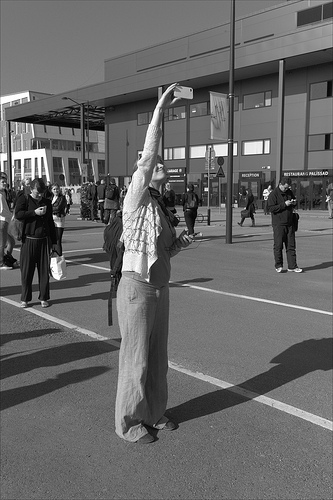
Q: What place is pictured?
A: It is a road.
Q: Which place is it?
A: It is a road.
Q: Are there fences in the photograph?
A: No, there are no fences.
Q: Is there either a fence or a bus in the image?
A: No, there are no fences or buses.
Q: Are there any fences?
A: No, there are no fences.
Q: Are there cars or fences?
A: No, there are no fences or cars.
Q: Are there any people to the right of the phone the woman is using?
A: Yes, there are people to the right of the phone.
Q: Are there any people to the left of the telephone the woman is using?
A: No, the people are to the right of the telephone.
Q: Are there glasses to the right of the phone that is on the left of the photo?
A: No, there are people to the right of the telephone.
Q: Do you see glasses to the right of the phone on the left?
A: No, there are people to the right of the telephone.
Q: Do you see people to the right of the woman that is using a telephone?
A: Yes, there are people to the right of the woman.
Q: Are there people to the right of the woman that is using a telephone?
A: Yes, there are people to the right of the woman.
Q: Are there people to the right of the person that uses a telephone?
A: Yes, there are people to the right of the woman.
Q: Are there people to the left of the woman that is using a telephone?
A: No, the people are to the right of the woman.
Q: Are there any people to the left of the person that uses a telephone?
A: No, the people are to the right of the woman.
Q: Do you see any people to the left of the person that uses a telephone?
A: No, the people are to the right of the woman.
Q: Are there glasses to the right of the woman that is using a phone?
A: No, there are people to the right of the woman.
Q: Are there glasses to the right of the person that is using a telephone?
A: No, there are people to the right of the woman.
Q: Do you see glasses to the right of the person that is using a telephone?
A: No, there are people to the right of the woman.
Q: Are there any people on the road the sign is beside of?
A: Yes, there are people on the road.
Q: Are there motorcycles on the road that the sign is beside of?
A: No, there are people on the road.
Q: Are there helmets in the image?
A: No, there are no helmets.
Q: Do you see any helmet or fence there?
A: No, there are no helmets or fences.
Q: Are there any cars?
A: No, there are no cars.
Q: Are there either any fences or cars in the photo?
A: No, there are no cars or fences.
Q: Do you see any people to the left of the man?
A: Yes, there is a person to the left of the man.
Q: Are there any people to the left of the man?
A: Yes, there is a person to the left of the man.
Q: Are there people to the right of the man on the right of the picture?
A: No, the person is to the left of the man.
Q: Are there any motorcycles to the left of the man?
A: No, there is a person to the left of the man.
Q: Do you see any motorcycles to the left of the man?
A: No, there is a person to the left of the man.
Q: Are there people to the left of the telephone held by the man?
A: Yes, there is a person to the left of the phone.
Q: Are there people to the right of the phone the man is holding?
A: No, the person is to the left of the telephone.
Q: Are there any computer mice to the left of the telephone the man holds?
A: No, there is a person to the left of the phone.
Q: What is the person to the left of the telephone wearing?
A: The person is wearing a bag.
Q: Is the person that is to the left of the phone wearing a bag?
A: Yes, the person is wearing a bag.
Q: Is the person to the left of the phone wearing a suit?
A: No, the person is wearing a bag.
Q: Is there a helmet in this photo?
A: No, there are no helmets.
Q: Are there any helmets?
A: No, there are no helmets.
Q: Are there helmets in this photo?
A: No, there are no helmets.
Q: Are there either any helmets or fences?
A: No, there are no helmets or fences.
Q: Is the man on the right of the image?
A: Yes, the man is on the right of the image.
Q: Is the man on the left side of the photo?
A: No, the man is on the right of the image.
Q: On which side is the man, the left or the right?
A: The man is on the right of the image.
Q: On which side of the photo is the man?
A: The man is on the right of the image.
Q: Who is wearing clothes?
A: The man is wearing clothes.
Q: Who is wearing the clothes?
A: The man is wearing clothes.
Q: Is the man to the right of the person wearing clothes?
A: Yes, the man is wearing clothes.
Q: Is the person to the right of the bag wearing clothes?
A: Yes, the man is wearing clothes.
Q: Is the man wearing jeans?
A: No, the man is wearing clothes.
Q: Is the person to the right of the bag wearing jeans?
A: No, the man is wearing clothes.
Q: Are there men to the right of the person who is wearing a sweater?
A: Yes, there is a man to the right of the person.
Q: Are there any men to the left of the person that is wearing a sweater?
A: No, the man is to the right of the person.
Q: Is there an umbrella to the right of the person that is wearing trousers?
A: No, there is a man to the right of the person.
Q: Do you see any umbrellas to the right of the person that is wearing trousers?
A: No, there is a man to the right of the person.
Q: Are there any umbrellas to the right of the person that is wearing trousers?
A: No, there is a man to the right of the person.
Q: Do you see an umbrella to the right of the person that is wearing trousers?
A: No, there is a man to the right of the person.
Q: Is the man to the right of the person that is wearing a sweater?
A: Yes, the man is to the right of the person.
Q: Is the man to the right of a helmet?
A: No, the man is to the right of the person.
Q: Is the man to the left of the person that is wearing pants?
A: No, the man is to the right of the person.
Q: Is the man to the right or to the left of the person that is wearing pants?
A: The man is to the right of the person.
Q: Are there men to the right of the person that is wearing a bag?
A: Yes, there is a man to the right of the person.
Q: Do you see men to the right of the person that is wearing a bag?
A: Yes, there is a man to the right of the person.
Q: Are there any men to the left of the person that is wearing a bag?
A: No, the man is to the right of the person.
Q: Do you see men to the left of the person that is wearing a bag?
A: No, the man is to the right of the person.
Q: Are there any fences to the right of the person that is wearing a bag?
A: No, there is a man to the right of the person.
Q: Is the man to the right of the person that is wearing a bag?
A: Yes, the man is to the right of the person.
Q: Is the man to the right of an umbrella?
A: No, the man is to the right of the person.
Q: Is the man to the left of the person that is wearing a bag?
A: No, the man is to the right of the person.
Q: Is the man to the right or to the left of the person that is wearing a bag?
A: The man is to the right of the person.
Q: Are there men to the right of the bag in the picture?
A: Yes, there is a man to the right of the bag.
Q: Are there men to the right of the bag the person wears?
A: Yes, there is a man to the right of the bag.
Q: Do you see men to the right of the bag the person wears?
A: Yes, there is a man to the right of the bag.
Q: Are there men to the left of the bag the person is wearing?
A: No, the man is to the right of the bag.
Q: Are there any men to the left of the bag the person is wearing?
A: No, the man is to the right of the bag.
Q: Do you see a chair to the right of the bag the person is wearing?
A: No, there is a man to the right of the bag.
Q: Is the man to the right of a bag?
A: Yes, the man is to the right of a bag.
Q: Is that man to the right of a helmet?
A: No, the man is to the right of a bag.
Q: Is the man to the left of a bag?
A: No, the man is to the right of a bag.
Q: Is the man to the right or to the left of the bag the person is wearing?
A: The man is to the right of the bag.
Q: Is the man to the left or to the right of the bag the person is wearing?
A: The man is to the right of the bag.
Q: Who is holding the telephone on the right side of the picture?
A: The man is holding the telephone.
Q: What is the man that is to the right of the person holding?
A: The man is holding the telephone.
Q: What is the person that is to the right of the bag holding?
A: The man is holding the telephone.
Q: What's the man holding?
A: The man is holding the telephone.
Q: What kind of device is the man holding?
A: The man is holding the phone.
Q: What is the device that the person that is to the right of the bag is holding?
A: The device is a phone.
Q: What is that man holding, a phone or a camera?
A: The man is holding a phone.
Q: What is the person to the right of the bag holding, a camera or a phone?
A: The man is holding a phone.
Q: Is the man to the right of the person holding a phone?
A: Yes, the man is holding a phone.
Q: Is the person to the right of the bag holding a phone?
A: Yes, the man is holding a phone.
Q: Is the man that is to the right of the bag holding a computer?
A: No, the man is holding a phone.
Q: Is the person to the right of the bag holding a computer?
A: No, the man is holding a phone.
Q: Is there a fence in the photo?
A: No, there are no fences.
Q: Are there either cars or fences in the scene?
A: No, there are no fences or cars.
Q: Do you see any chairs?
A: No, there are no chairs.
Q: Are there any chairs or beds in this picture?
A: No, there are no chairs or beds.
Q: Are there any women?
A: Yes, there is a woman.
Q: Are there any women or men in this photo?
A: Yes, there is a woman.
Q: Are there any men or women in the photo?
A: Yes, there is a woman.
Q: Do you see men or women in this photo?
A: Yes, there is a woman.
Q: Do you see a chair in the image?
A: No, there are no chairs.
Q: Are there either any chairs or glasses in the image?
A: No, there are no chairs or glasses.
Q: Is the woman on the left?
A: Yes, the woman is on the left of the image.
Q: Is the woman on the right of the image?
A: No, the woman is on the left of the image.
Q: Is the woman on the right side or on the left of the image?
A: The woman is on the left of the image.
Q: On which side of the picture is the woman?
A: The woman is on the left of the image.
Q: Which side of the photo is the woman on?
A: The woman is on the left of the image.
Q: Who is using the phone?
A: The woman is using the phone.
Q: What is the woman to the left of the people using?
A: The woman is using a phone.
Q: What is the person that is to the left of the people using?
A: The woman is using a phone.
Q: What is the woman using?
A: The woman is using a phone.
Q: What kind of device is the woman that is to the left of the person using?
A: The woman is using a telephone.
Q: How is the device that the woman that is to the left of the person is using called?
A: The device is a phone.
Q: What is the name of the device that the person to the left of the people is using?
A: The device is a phone.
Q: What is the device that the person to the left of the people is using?
A: The device is a phone.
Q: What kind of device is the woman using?
A: The woman is using a telephone.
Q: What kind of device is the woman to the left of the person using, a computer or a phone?
A: The woman is using a phone.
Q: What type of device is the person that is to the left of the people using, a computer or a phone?
A: The woman is using a phone.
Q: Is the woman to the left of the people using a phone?
A: Yes, the woman is using a phone.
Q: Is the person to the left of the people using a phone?
A: Yes, the woman is using a phone.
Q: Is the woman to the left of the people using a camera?
A: No, the woman is using a phone.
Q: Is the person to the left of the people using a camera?
A: No, the woman is using a phone.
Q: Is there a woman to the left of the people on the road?
A: Yes, there is a woman to the left of the people.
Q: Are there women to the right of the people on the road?
A: No, the woman is to the left of the people.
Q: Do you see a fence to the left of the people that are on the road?
A: No, there is a woman to the left of the people.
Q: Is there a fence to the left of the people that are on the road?
A: No, there is a woman to the left of the people.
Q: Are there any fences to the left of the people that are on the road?
A: No, there is a woman to the left of the people.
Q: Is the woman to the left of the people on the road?
A: Yes, the woman is to the left of the people.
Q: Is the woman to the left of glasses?
A: No, the woman is to the left of the people.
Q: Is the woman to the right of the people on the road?
A: No, the woman is to the left of the people.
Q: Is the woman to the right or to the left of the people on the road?
A: The woman is to the left of the people.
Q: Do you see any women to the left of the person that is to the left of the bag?
A: Yes, there is a woman to the left of the person.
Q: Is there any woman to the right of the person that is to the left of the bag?
A: No, the woman is to the left of the person.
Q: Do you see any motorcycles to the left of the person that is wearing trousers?
A: No, there is a woman to the left of the person.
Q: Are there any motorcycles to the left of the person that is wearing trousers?
A: No, there is a woman to the left of the person.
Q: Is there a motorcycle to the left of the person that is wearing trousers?
A: No, there is a woman to the left of the person.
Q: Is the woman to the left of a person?
A: Yes, the woman is to the left of a person.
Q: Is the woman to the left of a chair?
A: No, the woman is to the left of a person.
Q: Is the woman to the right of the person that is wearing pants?
A: No, the woman is to the left of the person.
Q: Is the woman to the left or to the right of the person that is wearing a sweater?
A: The woman is to the left of the person.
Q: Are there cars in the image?
A: No, there are no cars.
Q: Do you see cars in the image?
A: No, there are no cars.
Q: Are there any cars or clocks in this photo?
A: No, there are no cars or clocks.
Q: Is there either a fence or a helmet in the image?
A: No, there are no helmets or fences.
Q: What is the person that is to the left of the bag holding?
A: The person is holding the telephone.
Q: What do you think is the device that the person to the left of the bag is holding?
A: The device is a phone.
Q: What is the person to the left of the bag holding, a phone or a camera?
A: The person is holding a phone.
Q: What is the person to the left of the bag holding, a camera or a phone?
A: The person is holding a phone.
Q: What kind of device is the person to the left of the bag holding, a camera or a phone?
A: The person is holding a phone.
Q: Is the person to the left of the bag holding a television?
A: No, the person is holding the telephone.